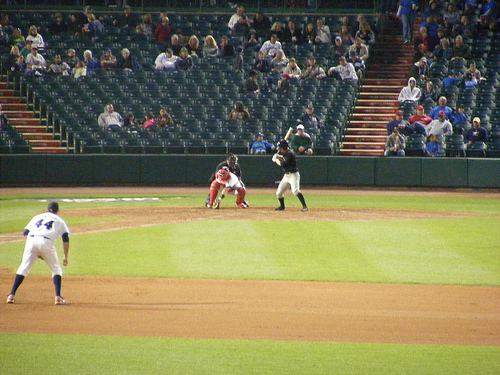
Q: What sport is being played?
A: Baseball.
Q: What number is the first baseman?
A: 44.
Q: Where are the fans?
A: In the stands.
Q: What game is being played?
A: Baseball.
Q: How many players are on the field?
A: Four.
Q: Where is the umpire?
A: Home plate.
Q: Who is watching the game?
A: Fans.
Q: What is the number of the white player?
A: Forty-four.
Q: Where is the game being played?
A: Stadium.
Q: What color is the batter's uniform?
A: Black.